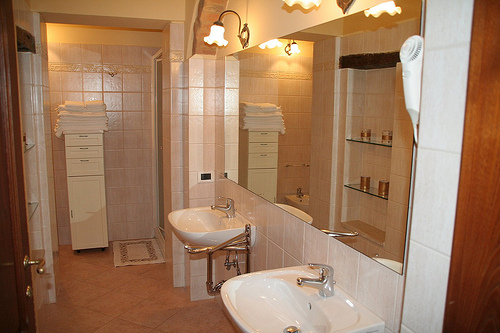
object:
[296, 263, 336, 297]
faucet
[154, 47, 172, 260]
door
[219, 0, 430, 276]
mirror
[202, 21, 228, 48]
light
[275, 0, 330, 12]
light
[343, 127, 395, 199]
sky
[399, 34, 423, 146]
air freshener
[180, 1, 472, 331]
wall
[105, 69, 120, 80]
hook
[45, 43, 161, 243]
tile wall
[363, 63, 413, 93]
ground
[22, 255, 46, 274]
gold handle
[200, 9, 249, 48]
light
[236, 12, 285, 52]
wall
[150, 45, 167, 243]
shower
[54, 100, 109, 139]
stack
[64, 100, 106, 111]
towel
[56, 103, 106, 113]
towel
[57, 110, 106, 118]
towel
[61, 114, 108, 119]
towel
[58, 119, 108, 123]
towel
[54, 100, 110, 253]
cabinet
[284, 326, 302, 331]
drain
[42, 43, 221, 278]
wall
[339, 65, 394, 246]
reflection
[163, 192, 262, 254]
utility pole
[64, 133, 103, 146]
drawer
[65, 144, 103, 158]
drawer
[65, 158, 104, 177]
drawer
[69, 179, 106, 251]
drawer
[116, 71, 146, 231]
tile wall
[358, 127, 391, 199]
bottles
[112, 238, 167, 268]
rug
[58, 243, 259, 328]
floor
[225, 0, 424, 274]
mirror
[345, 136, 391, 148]
shelve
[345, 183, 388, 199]
shelve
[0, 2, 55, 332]
brown door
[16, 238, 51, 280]
door handle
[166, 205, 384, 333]
sinks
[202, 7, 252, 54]
light fixture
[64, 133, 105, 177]
drawers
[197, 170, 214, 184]
outlet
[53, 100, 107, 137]
towels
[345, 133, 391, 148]
shelf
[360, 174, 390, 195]
shelf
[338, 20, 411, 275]
wall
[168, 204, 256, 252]
basin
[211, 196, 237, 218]
faucet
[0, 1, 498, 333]
bathroom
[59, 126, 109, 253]
cabinet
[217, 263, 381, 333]
sink